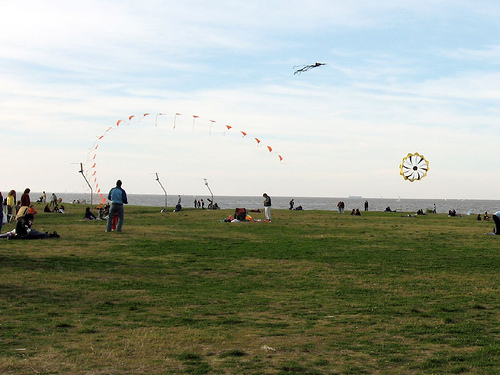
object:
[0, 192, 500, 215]
gray sea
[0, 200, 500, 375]
grass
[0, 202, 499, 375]
lake front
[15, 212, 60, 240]
people sitting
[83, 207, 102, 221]
people sitting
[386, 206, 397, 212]
people sitting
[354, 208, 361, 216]
people sitting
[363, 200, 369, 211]
people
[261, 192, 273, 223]
person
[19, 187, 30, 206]
person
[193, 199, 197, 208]
person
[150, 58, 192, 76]
clouds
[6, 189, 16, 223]
woman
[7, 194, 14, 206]
yellow sweater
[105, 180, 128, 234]
man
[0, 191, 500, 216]
lake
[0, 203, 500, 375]
ground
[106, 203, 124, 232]
jeans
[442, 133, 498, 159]
clouds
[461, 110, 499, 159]
clouds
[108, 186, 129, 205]
jacket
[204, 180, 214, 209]
pole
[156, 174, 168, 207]
pole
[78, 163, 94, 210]
pole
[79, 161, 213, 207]
row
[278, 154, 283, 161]
kites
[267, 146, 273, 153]
kites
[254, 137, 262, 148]
kites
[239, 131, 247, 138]
kites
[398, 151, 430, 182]
kite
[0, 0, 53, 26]
clouds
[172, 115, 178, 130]
tail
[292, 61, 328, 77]
kite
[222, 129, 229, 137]
tassels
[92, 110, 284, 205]
banner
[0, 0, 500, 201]
sky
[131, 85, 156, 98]
cloud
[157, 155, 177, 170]
cloud